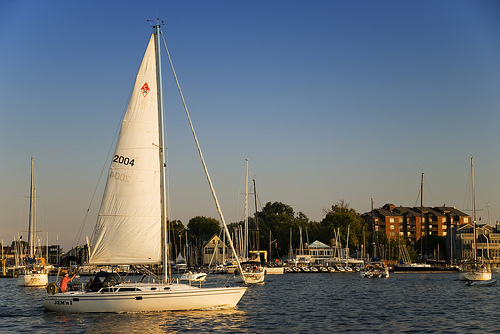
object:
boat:
[43, 10, 252, 314]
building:
[360, 203, 500, 269]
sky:
[0, 0, 499, 257]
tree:
[237, 199, 321, 271]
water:
[331, 285, 419, 329]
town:
[0, 183, 500, 281]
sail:
[80, 33, 167, 266]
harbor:
[0, 231, 499, 333]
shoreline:
[0, 253, 499, 278]